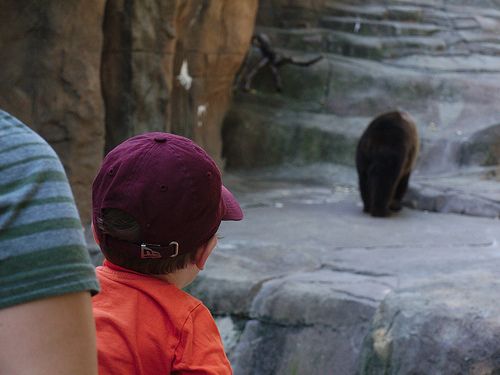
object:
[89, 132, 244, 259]
hat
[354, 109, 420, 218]
bear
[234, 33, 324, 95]
branch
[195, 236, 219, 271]
ear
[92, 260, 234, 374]
shirt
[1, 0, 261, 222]
rock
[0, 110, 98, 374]
arm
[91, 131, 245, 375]
boy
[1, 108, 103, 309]
shirt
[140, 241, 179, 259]
buckle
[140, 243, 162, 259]
logo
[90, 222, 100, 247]
ear